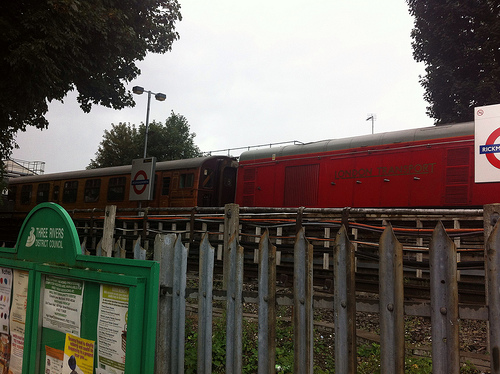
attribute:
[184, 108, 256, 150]
cloud —  white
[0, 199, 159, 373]
board —  green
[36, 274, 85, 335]
notices —   public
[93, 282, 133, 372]
notices —   public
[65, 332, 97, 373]
notices —   public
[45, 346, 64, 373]
notices —   public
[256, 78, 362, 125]
clouds — white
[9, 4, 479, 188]
sky — blue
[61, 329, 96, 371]
flyer —  White and yellow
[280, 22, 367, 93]
sky —  blue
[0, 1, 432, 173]
clouds —  white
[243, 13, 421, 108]
clouds — white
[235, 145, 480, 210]
car train —  Two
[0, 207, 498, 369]
picket fence —  picket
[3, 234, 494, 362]
tracks —  railroad's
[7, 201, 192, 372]
board — green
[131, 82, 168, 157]
street lamp — for street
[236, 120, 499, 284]
train car —  red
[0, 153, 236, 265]
train car —  red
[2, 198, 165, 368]
frame —  green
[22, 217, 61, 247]
lettering —  White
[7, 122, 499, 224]
train —  red 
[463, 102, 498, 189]
sign —  white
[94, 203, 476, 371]
fence —   metal,  Rusted, wooden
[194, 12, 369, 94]
sky —  blue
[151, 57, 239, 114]
cloud —  white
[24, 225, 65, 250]
sign —   THREE RIVERS DISTRICT COUNCIL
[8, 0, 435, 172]
sky —  blue, blue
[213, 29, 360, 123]
sky —  blue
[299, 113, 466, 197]
car —  train's , with LONDON TRANSPORT 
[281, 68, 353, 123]
clouds —  white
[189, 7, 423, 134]
sky —  blue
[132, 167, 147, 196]
circle —   red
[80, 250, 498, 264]
track —  train's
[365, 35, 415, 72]
clouds —  white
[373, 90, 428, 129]
clouds —  white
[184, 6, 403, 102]
cloud — white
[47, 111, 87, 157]
sky — blue